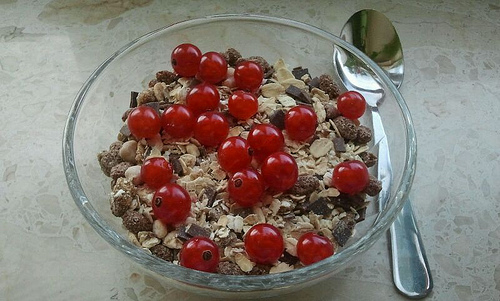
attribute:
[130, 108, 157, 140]
cherry — red, round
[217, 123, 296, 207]
red berries — red 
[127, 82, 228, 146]
red berries — red 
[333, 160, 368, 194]
red berries — red 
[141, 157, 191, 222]
red berries — red 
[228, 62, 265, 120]
red berries — red 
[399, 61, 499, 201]
counter — stone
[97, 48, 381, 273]
oatmeal flakes — pictured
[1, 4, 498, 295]
white counter — WHITE 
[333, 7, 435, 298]
spoon — metal, silver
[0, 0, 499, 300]
surface — granite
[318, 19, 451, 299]
spoon — long, silver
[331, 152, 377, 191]
cherry — red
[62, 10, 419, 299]
bowl — clear, glass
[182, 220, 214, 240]
chocolate chip — pictured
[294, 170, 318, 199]
chocolate chip — pictured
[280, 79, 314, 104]
chocolate chip — pictured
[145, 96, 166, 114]
chocolate chip — pictured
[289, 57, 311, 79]
chocolate chip — pictured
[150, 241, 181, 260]
raisins — brown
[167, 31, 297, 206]
cherries — red 